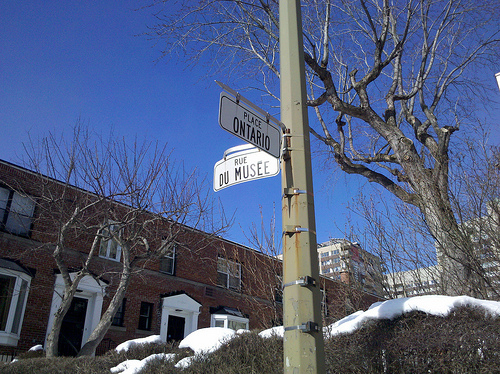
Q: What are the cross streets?
A: Rue du Musee and Place Ontario.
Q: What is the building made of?
A: Brick.